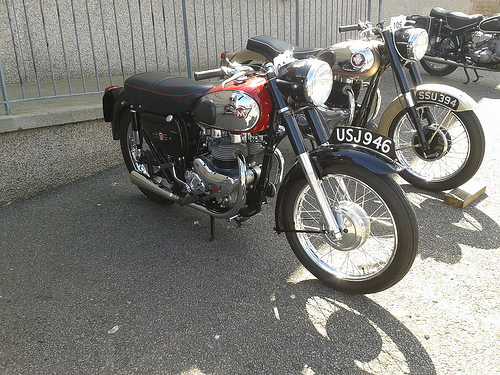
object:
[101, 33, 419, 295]
bike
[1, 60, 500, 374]
street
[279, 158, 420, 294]
front tire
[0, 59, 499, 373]
shadow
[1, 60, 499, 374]
ground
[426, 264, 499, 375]
light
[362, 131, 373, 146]
number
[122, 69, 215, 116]
seat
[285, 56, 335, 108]
light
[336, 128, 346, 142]
letters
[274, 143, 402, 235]
fender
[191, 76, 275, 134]
gas tank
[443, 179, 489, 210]
block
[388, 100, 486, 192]
tire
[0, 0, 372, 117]
railing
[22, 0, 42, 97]
rod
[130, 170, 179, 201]
exhaust pipe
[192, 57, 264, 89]
handlebar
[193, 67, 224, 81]
handle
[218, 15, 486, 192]
motorcycle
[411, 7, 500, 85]
motorcycle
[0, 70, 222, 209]
ramp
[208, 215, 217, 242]
kick stand